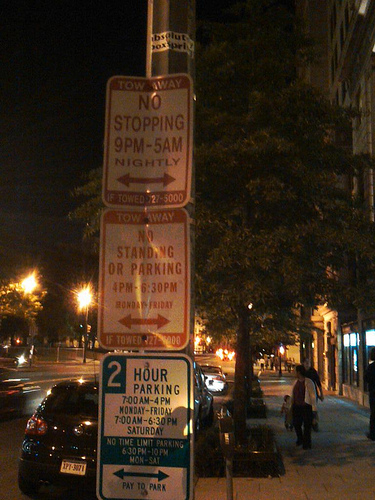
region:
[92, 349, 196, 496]
a blue and white sign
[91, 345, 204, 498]
sign has blue border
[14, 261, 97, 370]
two lights on left street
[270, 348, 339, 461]
people walking on the street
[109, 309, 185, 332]
a red arrow on sign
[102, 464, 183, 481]
a blue arrow on sign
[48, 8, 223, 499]
three signs on a pole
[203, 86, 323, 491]
a tall tree by street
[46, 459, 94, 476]
a plate on a car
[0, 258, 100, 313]
two street lights on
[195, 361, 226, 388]
a parked white car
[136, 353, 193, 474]
a shadow on a sign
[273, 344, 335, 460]
people on the sidewalk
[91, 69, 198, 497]
three signs attached to a pole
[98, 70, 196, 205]
a red and white traffic sign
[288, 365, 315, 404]
a person wearing a white jacket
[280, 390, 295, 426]
a small child walking on a sidewalk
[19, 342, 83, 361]
a chain link fence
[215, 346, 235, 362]
several cars with headlights on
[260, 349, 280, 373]
several people standing on the sidewalk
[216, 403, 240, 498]
a parking meter next to a road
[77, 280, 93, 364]
a tall street light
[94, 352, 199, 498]
a green and white traffic sign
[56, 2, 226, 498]
a pole with multiple signs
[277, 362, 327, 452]
this is a woman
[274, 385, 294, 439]
this is a child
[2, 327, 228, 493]
cars parked on the side of road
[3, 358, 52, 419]
car driving on the street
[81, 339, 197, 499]
a white and blue sign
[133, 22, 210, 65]
sticker on the pole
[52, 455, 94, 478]
a white licence plate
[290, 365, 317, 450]
a person wearing a white jacket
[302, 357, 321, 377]
a man wearing a black shirt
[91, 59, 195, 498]
three traffic signs on a post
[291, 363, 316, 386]
a person looking over their shoulder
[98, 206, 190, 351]
a red and white sign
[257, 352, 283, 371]
several people standing together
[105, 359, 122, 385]
White number 2 on blue background.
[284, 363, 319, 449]
Black haired woman in white coat.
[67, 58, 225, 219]
sign above the land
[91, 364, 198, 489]
words on the sign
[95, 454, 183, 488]
arrows on the sign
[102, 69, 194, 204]
sign is on the pole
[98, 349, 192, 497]
sign is on the pole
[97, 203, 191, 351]
sign is on the pole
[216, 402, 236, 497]
parking meter is beside the road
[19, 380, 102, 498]
car is parked beside the sidewalk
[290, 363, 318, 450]
lady is walking on sidewalk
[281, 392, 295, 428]
kid is walking on side walk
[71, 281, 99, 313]
light flare is bright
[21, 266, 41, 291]
light flare is bright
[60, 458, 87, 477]
license plate is on the back of car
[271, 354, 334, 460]
a family walking on the street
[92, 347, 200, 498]
the sign is white and green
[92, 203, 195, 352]
the sign is red and white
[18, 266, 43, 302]
a light in the street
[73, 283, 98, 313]
a light in the street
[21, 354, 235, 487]
car parking on teh side road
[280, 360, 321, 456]
woman wears a white jacket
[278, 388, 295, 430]
a little boy on the street